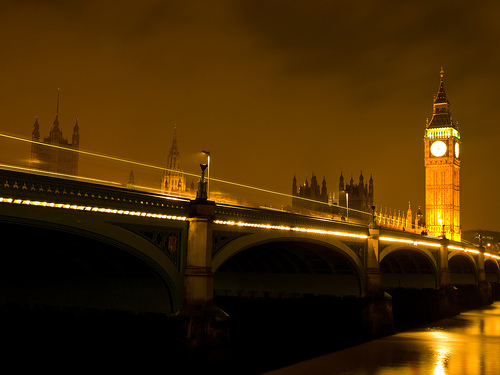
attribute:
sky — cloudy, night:
[2, 1, 427, 84]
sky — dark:
[1, 0, 498, 235]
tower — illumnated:
[421, 55, 466, 245]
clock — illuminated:
[430, 137, 452, 154]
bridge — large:
[1, 131, 499, 310]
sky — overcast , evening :
[17, 17, 423, 99]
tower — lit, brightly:
[423, 62, 462, 242]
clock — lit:
[429, 140, 448, 157]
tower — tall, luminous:
[419, 65, 462, 239]